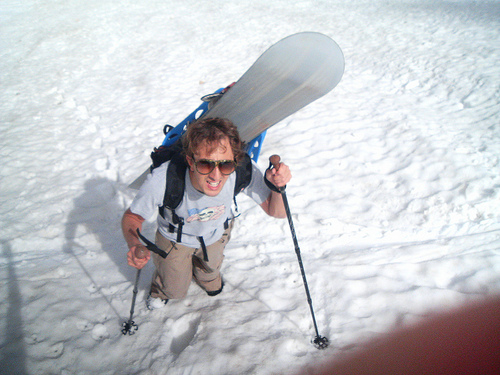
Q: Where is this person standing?
A: In the snow.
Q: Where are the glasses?
A: On his face.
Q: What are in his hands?
A: Ski poles.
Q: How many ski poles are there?
A: Two.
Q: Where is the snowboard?
A: On his back.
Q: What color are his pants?
A: Tan.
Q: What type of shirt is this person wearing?
A: A t-shirt.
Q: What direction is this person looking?
A: Up.